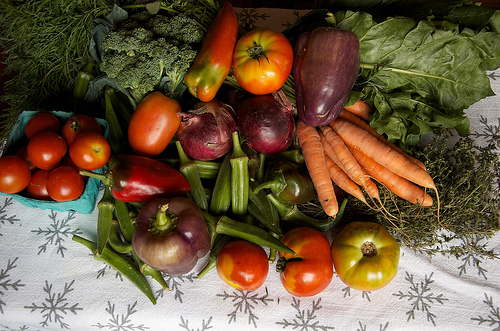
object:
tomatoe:
[45, 165, 85, 203]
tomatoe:
[67, 130, 112, 171]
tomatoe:
[60, 114, 104, 149]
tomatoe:
[23, 112, 62, 141]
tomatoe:
[25, 169, 56, 202]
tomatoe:
[329, 219, 404, 295]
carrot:
[295, 119, 341, 222]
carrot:
[337, 105, 429, 171]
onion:
[174, 99, 238, 162]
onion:
[235, 88, 298, 156]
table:
[0, 0, 500, 331]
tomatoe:
[273, 225, 335, 299]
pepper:
[251, 158, 317, 206]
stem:
[251, 168, 288, 198]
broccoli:
[98, 11, 208, 111]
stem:
[274, 255, 287, 273]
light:
[365, 269, 385, 283]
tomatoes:
[25, 131, 70, 172]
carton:
[0, 109, 112, 216]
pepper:
[290, 11, 364, 129]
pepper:
[77, 153, 194, 204]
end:
[77, 168, 114, 187]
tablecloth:
[0, 66, 500, 331]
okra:
[227, 131, 250, 223]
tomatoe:
[231, 27, 295, 96]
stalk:
[241, 40, 272, 67]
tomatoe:
[126, 90, 185, 159]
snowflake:
[22, 278, 86, 331]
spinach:
[320, 8, 500, 118]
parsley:
[329, 113, 500, 283]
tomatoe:
[214, 237, 271, 293]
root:
[431, 184, 452, 234]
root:
[375, 195, 412, 226]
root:
[412, 185, 430, 221]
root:
[365, 183, 388, 212]